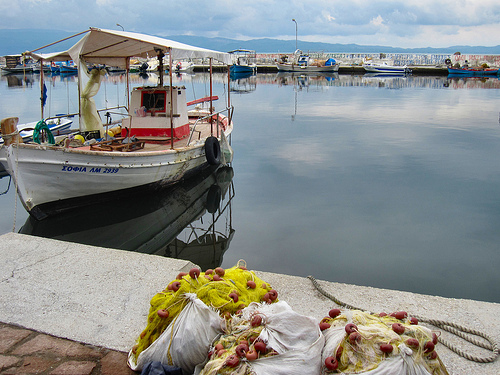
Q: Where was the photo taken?
A: Near a dock.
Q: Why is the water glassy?
A: There are no waves.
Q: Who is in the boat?
A: No one.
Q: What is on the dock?
A: Fishing nets.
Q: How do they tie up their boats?
A: With rope.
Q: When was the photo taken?
A: Daytime.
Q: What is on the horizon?
A: Mountains.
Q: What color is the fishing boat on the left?
A: White and red.